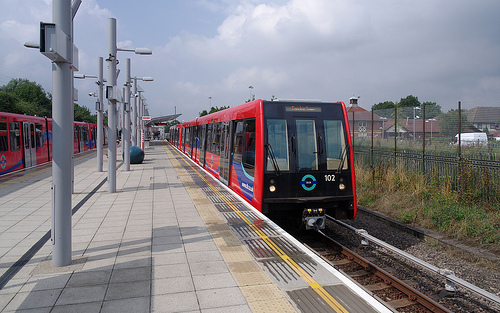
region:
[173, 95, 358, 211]
train on the track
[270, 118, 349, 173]
front window to the train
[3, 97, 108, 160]
train on opposite track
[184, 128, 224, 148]
windows on side of train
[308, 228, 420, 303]
track train rides on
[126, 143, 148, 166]
ball on train platform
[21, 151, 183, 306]
platform of train area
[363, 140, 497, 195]
fence near train track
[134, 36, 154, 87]
lights on train platform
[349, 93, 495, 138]
buildings in the distance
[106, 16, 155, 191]
gray pole with street light on it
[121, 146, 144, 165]
round blue-green object like a large ball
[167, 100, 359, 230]
red and black passenger train with many windows and the number 102 on the front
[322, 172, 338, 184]
white number 102 on a black background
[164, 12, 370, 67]
cloud in an ominous gray sky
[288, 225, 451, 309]
raileay tracks, brown with gravel mixed amongst its parts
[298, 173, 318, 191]
light blue and dark blue circle on black background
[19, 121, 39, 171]
passenger train sliding double doors, grayish on red background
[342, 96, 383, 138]
ligth brown square shaoed building with pointy roof and square chimney-like edifice on the top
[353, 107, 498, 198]
wire fencing with square slats and brown poles on top on black railing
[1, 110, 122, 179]
red and blue train without the engine car visible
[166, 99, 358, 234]
red and blue train that is fully visible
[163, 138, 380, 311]
textured safety strip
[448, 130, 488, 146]
white paneled van in the background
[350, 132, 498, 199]
field of tall overgrown grass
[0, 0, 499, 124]
large bank of white and grey clouds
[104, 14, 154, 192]
silver light pole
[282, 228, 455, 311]
rusty metal train track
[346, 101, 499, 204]
tall fencing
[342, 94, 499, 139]
homes in the background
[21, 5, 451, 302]
commuter train station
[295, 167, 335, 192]
logo of company and train number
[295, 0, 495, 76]
gray clouds in the sky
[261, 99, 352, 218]
first car in the train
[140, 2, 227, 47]
patch of clearer sky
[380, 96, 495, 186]
tall fence at the edge of the tracks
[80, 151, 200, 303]
the station's platform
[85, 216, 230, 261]
shadow of utility pole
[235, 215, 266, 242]
yellow caution line on the platform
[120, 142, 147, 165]
dark blue garbage disposal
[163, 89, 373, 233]
train on the tracks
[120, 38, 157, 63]
street light on the pole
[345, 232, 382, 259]
dirt between the tracks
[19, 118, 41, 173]
doors on the train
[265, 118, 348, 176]
three windows on the train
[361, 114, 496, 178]
fence on the side of the train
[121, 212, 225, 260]
shadow on the ground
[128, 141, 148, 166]
blue ball on the ground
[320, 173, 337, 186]
number 102 on the front of the train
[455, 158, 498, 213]
green bush in front of the fence